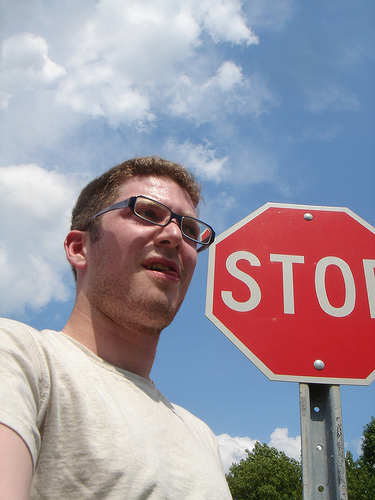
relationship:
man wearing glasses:
[0, 157, 234, 499] [82, 193, 217, 254]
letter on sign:
[218, 248, 262, 312] [205, 203, 374, 388]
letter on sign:
[268, 252, 305, 315] [205, 203, 374, 388]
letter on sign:
[312, 254, 355, 318] [205, 203, 374, 388]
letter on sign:
[360, 257, 373, 322] [205, 203, 374, 388]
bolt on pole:
[313, 359, 324, 370] [295, 382, 348, 498]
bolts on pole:
[304, 212, 313, 220] [295, 382, 348, 498]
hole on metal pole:
[311, 404, 321, 416] [296, 382, 347, 498]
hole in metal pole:
[314, 443, 322, 453] [296, 382, 347, 498]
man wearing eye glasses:
[0, 157, 234, 497] [91, 195, 213, 253]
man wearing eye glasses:
[0, 157, 234, 497] [86, 195, 215, 252]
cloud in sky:
[0, 0, 365, 476] [1, 2, 373, 477]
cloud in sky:
[68, 31, 140, 53] [237, 44, 373, 169]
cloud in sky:
[0, 0, 365, 476] [217, 54, 344, 132]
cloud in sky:
[0, 0, 365, 476] [74, 38, 296, 115]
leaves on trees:
[252, 448, 279, 460] [223, 435, 288, 499]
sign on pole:
[207, 187, 372, 358] [297, 375, 345, 499]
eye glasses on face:
[86, 195, 215, 252] [96, 169, 214, 332]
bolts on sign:
[301, 210, 320, 370] [218, 191, 372, 412]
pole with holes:
[292, 373, 362, 499] [311, 401, 325, 452]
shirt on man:
[19, 326, 230, 499] [19, 137, 257, 498]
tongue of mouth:
[161, 269, 182, 277] [140, 244, 185, 285]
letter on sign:
[220, 251, 261, 313] [208, 191, 373, 394]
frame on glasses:
[123, 194, 141, 210] [117, 176, 221, 251]